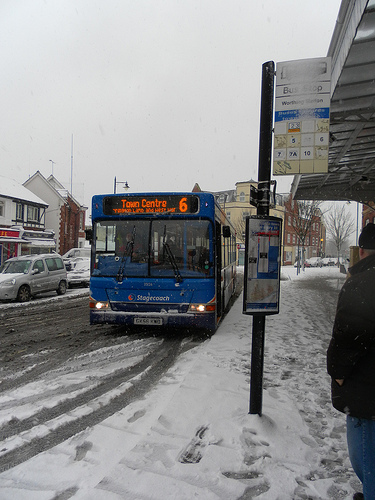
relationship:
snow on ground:
[1, 267, 360, 498] [2, 255, 374, 499]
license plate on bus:
[132, 315, 162, 327] [86, 191, 241, 334]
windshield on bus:
[89, 214, 219, 285] [86, 191, 241, 334]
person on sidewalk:
[324, 219, 374, 500] [88, 275, 373, 499]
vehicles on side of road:
[1, 251, 69, 308] [3, 255, 251, 497]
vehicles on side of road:
[66, 256, 93, 288] [3, 255, 251, 497]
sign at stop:
[235, 213, 288, 324] [87, 1, 373, 500]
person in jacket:
[324, 219, 374, 500] [324, 257, 375, 420]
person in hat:
[324, 219, 374, 500] [355, 222, 374, 250]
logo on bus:
[133, 294, 172, 303] [86, 191, 241, 334]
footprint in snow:
[220, 467, 260, 481] [1, 267, 360, 498]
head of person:
[353, 223, 374, 265] [324, 219, 374, 500]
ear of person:
[353, 244, 364, 256] [324, 219, 374, 500]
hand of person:
[329, 371, 345, 386] [324, 219, 374, 500]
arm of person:
[324, 276, 365, 384] [324, 219, 374, 500]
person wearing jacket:
[324, 219, 374, 500] [324, 257, 375, 420]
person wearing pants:
[324, 219, 374, 500] [342, 409, 374, 500]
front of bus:
[89, 192, 217, 328] [86, 191, 241, 334]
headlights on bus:
[192, 301, 205, 315] [86, 191, 241, 334]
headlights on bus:
[90, 302, 106, 312] [86, 191, 241, 334]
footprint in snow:
[235, 480, 273, 499] [1, 267, 360, 498]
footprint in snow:
[240, 449, 272, 465] [1, 267, 360, 498]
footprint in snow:
[243, 434, 272, 450] [1, 267, 360, 498]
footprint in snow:
[69, 437, 94, 464] [1, 267, 360, 498]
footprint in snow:
[45, 482, 80, 500] [1, 267, 360, 498]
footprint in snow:
[127, 406, 149, 426] [1, 267, 360, 498]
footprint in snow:
[324, 481, 351, 500] [1, 267, 360, 498]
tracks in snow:
[175, 421, 218, 468] [1, 267, 360, 498]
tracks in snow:
[2, 332, 189, 472] [1, 267, 360, 498]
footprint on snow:
[235, 480, 273, 499] [1, 267, 360, 498]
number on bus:
[178, 195, 189, 213] [86, 191, 241, 334]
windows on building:
[26, 205, 43, 224] [1, 173, 60, 280]